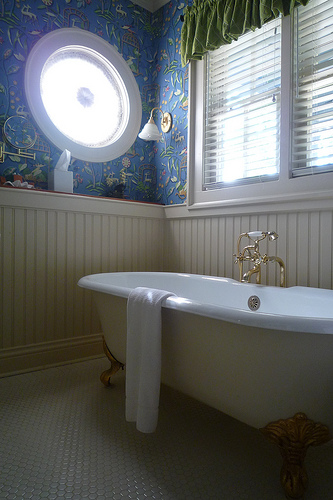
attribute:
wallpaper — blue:
[124, 24, 190, 72]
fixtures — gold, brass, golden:
[233, 230, 296, 293]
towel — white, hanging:
[119, 289, 170, 445]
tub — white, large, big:
[83, 266, 330, 428]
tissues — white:
[52, 149, 83, 196]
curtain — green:
[176, 0, 276, 45]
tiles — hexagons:
[44, 430, 64, 442]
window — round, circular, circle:
[38, 30, 145, 165]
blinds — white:
[221, 45, 317, 159]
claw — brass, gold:
[94, 343, 122, 385]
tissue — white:
[50, 145, 73, 192]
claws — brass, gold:
[255, 412, 322, 498]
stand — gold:
[88, 336, 121, 399]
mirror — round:
[5, 112, 35, 148]